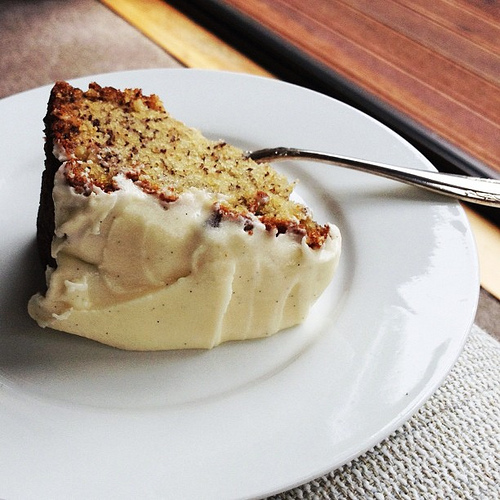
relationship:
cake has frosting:
[25, 79, 342, 350] [25, 163, 344, 353]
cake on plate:
[25, 79, 342, 350] [3, 68, 479, 499]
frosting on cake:
[25, 163, 344, 353] [25, 79, 342, 350]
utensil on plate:
[243, 145, 498, 207] [3, 68, 479, 499]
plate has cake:
[3, 68, 479, 499] [25, 79, 342, 350]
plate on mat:
[3, 68, 479, 499] [257, 323, 498, 497]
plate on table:
[3, 68, 479, 499] [1, 2, 499, 346]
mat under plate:
[257, 323, 498, 497] [3, 68, 479, 499]